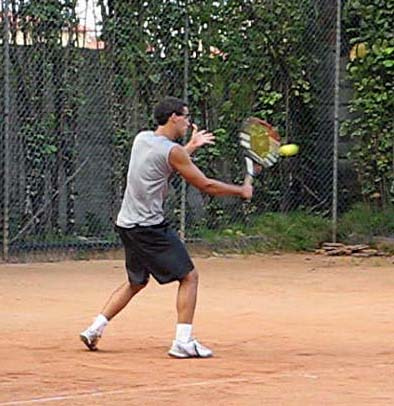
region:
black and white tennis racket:
[224, 100, 306, 208]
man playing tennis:
[75, 78, 305, 376]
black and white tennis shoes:
[159, 315, 236, 372]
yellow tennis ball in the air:
[271, 127, 317, 178]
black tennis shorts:
[103, 196, 227, 316]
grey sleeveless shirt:
[106, 116, 192, 235]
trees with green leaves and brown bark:
[18, 9, 118, 254]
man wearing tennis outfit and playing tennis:
[57, 61, 300, 389]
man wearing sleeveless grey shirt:
[58, 86, 301, 378]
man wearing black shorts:
[68, 75, 308, 369]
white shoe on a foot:
[161, 335, 221, 364]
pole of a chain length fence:
[322, 85, 348, 184]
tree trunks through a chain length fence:
[27, 80, 129, 154]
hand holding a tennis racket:
[227, 175, 263, 211]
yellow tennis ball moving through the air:
[262, 128, 313, 162]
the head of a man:
[152, 89, 192, 134]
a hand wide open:
[188, 118, 224, 148]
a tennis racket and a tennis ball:
[231, 107, 308, 176]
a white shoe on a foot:
[76, 322, 118, 350]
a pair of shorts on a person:
[105, 210, 209, 291]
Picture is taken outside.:
[11, 6, 392, 396]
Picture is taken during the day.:
[24, 96, 383, 390]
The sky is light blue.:
[9, 2, 194, 77]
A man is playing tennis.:
[77, 85, 293, 390]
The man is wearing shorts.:
[91, 232, 205, 296]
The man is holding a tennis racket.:
[227, 106, 294, 224]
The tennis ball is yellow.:
[270, 128, 309, 165]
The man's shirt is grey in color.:
[104, 117, 195, 238]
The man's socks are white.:
[70, 319, 228, 373]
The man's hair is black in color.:
[147, 98, 188, 126]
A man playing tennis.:
[68, 85, 297, 361]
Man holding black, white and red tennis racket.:
[222, 110, 281, 202]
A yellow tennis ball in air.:
[278, 138, 299, 162]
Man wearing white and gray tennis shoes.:
[76, 326, 214, 370]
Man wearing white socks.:
[93, 308, 199, 345]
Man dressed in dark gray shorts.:
[110, 214, 202, 287]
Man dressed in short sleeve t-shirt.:
[117, 130, 182, 234]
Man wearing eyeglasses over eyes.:
[175, 107, 193, 121]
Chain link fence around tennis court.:
[3, 21, 106, 250]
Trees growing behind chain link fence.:
[273, 12, 392, 229]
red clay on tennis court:
[44, 337, 134, 389]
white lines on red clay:
[72, 380, 173, 402]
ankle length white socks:
[166, 320, 202, 343]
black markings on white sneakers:
[168, 333, 229, 359]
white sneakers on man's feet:
[153, 332, 246, 370]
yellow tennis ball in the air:
[272, 136, 306, 164]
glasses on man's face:
[178, 111, 201, 126]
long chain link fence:
[27, 45, 113, 164]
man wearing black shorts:
[102, 209, 193, 303]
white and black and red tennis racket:
[231, 104, 295, 204]